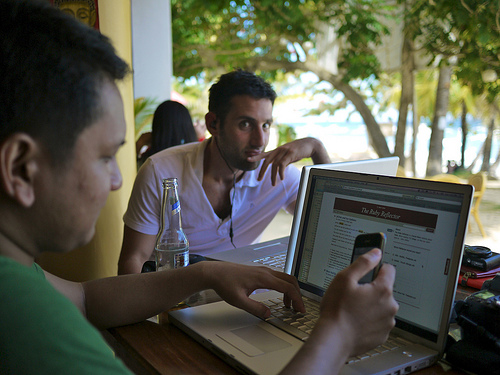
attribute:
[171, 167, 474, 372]
laptop — silver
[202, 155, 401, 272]
laptop — silver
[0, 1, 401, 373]
man — typing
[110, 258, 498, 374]
table — brown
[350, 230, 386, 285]
cell phone — black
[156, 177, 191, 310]
bottle — glass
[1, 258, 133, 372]
shirt — green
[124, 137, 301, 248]
shirt — white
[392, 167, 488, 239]
chairs — yellow